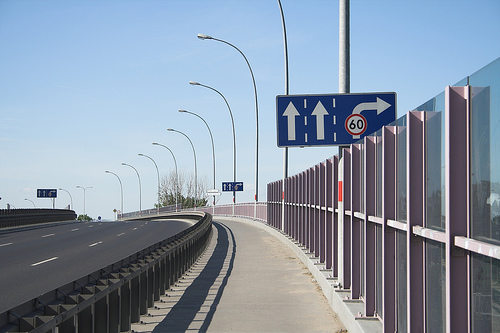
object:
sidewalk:
[121, 194, 329, 331]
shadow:
[193, 217, 239, 329]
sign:
[272, 92, 395, 147]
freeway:
[0, 221, 203, 331]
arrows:
[350, 96, 393, 140]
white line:
[89, 238, 104, 248]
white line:
[113, 227, 127, 238]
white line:
[28, 254, 56, 267]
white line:
[41, 231, 54, 239]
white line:
[70, 226, 80, 232]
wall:
[265, 59, 497, 331]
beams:
[442, 85, 471, 331]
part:
[213, 266, 218, 270]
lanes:
[0, 225, 126, 265]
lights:
[45, 0, 449, 212]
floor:
[125, 218, 345, 331]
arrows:
[282, 98, 328, 142]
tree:
[154, 165, 218, 208]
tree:
[74, 210, 94, 223]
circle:
[344, 114, 367, 133]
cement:
[179, 202, 349, 332]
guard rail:
[0, 212, 213, 324]